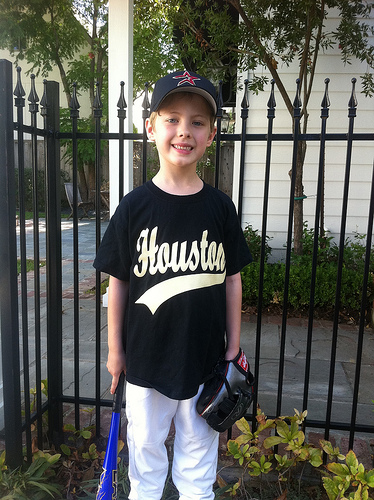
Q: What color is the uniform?
A: Black and white.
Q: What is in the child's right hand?
A: Blue bat.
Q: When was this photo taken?
A: Daytime.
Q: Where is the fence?
A: Behind the child.